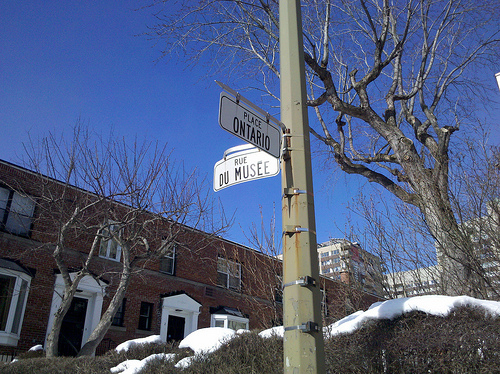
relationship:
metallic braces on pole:
[263, 267, 333, 295] [247, 5, 367, 372]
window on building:
[0, 187, 37, 237] [23, 146, 132, 348]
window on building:
[213, 253, 246, 293] [110, 203, 276, 355]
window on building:
[149, 242, 199, 287] [9, 160, 490, 370]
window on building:
[0, 187, 37, 237] [1, 159, 384, 356]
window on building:
[329, 246, 339, 258] [312, 236, 387, 296]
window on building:
[2, 217, 31, 237] [26, 118, 261, 353]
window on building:
[0, 268, 32, 339] [1, 159, 384, 356]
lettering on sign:
[231, 115, 271, 147] [213, 89, 287, 159]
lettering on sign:
[219, 162, 264, 187] [188, 99, 302, 197]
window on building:
[0, 187, 37, 237] [4, 160, 391, 372]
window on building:
[209, 245, 249, 295] [29, 162, 274, 340]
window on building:
[134, 297, 155, 336] [4, 160, 391, 372]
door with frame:
[44, 265, 119, 357] [79, 291, 102, 358]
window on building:
[0, 268, 34, 351] [5, 124, 285, 365]